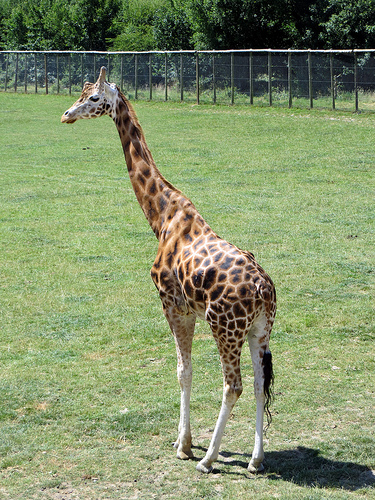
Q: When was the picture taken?
A: Daytime.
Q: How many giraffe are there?
A: One.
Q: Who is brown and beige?
A: A giraffe.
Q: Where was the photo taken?
A: On a grassy field.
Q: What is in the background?
A: Trees.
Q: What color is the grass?
A: Green.